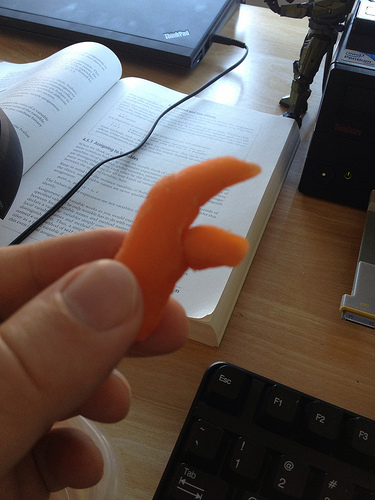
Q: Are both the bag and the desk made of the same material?
A: No, the bag is made of plastic and the desk is made of wood.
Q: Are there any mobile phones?
A: No, there are no mobile phones.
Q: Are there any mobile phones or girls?
A: No, there are no mobile phones or girls.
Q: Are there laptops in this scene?
A: Yes, there is a laptop.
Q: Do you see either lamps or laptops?
A: Yes, there is a laptop.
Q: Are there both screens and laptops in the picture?
A: No, there is a laptop but no screens.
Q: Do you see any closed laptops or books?
A: Yes, there is a closed laptop.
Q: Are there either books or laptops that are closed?
A: Yes, the laptop is closed.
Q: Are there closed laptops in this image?
A: Yes, there is a closed laptop.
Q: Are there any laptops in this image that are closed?
A: Yes, there is a laptop that is closed.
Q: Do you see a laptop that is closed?
A: Yes, there is a laptop that is closed.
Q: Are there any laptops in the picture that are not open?
A: Yes, there is an closed laptop.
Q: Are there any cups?
A: No, there are no cups.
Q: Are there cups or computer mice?
A: No, there are no cups or computer mice.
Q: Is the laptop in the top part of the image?
A: Yes, the laptop is in the top of the image.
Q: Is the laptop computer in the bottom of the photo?
A: No, the laptop computer is in the top of the image.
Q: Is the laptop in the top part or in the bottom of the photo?
A: The laptop is in the top of the image.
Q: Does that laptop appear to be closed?
A: Yes, the laptop is closed.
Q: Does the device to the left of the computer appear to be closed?
A: Yes, the laptop is closed.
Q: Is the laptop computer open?
A: No, the laptop computer is closed.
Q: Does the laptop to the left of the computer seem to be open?
A: No, the laptop computer is closed.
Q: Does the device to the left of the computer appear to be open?
A: No, the laptop computer is closed.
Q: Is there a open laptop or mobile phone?
A: No, there is a laptop but it is closed.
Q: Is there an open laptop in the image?
A: No, there is a laptop but it is closed.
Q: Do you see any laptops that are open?
A: No, there is a laptop but it is closed.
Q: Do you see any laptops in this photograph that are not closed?
A: No, there is a laptop but it is closed.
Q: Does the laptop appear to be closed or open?
A: The laptop is closed.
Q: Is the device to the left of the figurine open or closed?
A: The laptop is closed.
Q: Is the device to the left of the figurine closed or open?
A: The laptop is closed.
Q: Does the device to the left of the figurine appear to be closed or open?
A: The laptop is closed.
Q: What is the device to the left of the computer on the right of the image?
A: The device is a laptop.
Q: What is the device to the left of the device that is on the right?
A: The device is a laptop.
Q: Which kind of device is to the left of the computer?
A: The device is a laptop.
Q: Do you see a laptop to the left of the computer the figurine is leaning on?
A: Yes, there is a laptop to the left of the computer.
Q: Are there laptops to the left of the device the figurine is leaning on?
A: Yes, there is a laptop to the left of the computer.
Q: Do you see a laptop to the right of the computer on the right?
A: No, the laptop is to the left of the computer.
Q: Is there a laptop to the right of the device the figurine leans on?
A: No, the laptop is to the left of the computer.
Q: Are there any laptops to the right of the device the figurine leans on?
A: No, the laptop is to the left of the computer.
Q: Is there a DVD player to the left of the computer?
A: No, there is a laptop to the left of the computer.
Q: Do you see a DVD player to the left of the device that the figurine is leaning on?
A: No, there is a laptop to the left of the computer.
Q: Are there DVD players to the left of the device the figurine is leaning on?
A: No, there is a laptop to the left of the computer.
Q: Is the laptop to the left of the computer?
A: Yes, the laptop is to the left of the computer.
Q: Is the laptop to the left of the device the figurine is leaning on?
A: Yes, the laptop is to the left of the computer.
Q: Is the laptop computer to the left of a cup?
A: No, the laptop computer is to the left of the computer.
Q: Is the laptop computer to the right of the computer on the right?
A: No, the laptop computer is to the left of the computer.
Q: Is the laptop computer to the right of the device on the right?
A: No, the laptop computer is to the left of the computer.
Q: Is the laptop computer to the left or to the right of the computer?
A: The laptop computer is to the left of the computer.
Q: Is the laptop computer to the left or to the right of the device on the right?
A: The laptop computer is to the left of the computer.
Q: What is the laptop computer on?
A: The laptop computer is on the desk.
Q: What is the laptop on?
A: The laptop computer is on the desk.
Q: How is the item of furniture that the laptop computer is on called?
A: The piece of furniture is a desk.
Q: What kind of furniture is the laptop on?
A: The laptop computer is on the desk.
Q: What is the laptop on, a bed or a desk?
A: The laptop is on a desk.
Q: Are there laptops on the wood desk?
A: Yes, there is a laptop on the desk.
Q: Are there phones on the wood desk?
A: No, there is a laptop on the desk.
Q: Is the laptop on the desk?
A: Yes, the laptop is on the desk.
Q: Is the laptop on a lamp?
A: No, the laptop is on the desk.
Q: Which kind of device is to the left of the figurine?
A: The device is a laptop.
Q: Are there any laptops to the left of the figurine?
A: Yes, there is a laptop to the left of the figurine.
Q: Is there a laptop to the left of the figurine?
A: Yes, there is a laptop to the left of the figurine.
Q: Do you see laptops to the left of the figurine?
A: Yes, there is a laptop to the left of the figurine.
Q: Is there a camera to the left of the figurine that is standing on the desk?
A: No, there is a laptop to the left of the figurine.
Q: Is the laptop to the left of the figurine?
A: Yes, the laptop is to the left of the figurine.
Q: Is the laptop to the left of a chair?
A: No, the laptop is to the left of the figurine.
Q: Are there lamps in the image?
A: No, there are no lamps.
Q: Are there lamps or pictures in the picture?
A: No, there are no lamps or pictures.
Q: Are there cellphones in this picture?
A: No, there are no cellphones.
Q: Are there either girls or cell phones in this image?
A: No, there are no cell phones or girls.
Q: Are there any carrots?
A: Yes, there is a carrot.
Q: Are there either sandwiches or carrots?
A: Yes, there is a carrot.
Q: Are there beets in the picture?
A: No, there are no beets.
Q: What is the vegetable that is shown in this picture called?
A: The vegetable is a carrot.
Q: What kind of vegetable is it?
A: The vegetable is a carrot.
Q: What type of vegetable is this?
A: This is a carrot.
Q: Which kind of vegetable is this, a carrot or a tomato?
A: This is a carrot.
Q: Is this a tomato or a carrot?
A: This is a carrot.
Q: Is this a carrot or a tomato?
A: This is a carrot.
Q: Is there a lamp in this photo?
A: No, there are no lamps.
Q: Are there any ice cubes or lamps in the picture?
A: No, there are no lamps or ice cubes.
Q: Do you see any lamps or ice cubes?
A: No, there are no lamps or ice cubes.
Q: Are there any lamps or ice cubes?
A: No, there are no lamps or ice cubes.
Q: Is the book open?
A: Yes, the book is open.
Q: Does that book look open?
A: Yes, the book is open.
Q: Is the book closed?
A: No, the book is open.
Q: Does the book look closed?
A: No, the book is open.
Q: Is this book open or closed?
A: The book is open.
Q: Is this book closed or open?
A: The book is open.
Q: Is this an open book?
A: Yes, this is an open book.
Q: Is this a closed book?
A: No, this is an open book.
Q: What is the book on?
A: The book is on the desk.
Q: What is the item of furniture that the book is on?
A: The piece of furniture is a desk.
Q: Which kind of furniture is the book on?
A: The book is on the desk.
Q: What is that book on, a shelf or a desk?
A: The book is on a desk.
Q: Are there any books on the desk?
A: Yes, there is a book on the desk.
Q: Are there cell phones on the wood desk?
A: No, there is a book on the desk.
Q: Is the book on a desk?
A: Yes, the book is on a desk.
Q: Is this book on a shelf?
A: No, the book is on a desk.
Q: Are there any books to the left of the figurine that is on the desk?
A: Yes, there is a book to the left of the figurine.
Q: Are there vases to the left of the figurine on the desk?
A: No, there is a book to the left of the figurine.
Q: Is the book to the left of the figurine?
A: Yes, the book is to the left of the figurine.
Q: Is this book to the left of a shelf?
A: No, the book is to the left of the figurine.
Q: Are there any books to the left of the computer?
A: Yes, there is a book to the left of the computer.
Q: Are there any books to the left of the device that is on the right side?
A: Yes, there is a book to the left of the computer.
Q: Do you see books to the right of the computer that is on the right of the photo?
A: No, the book is to the left of the computer.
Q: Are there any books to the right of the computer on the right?
A: No, the book is to the left of the computer.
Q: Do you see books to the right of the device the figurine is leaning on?
A: No, the book is to the left of the computer.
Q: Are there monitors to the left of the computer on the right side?
A: No, there is a book to the left of the computer.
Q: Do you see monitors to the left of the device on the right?
A: No, there is a book to the left of the computer.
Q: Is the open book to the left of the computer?
A: Yes, the book is to the left of the computer.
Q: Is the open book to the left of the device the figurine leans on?
A: Yes, the book is to the left of the computer.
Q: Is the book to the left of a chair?
A: No, the book is to the left of the computer.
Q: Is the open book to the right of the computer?
A: No, the book is to the left of the computer.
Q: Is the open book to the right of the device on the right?
A: No, the book is to the left of the computer.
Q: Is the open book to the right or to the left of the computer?
A: The book is to the left of the computer.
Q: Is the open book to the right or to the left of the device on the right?
A: The book is to the left of the computer.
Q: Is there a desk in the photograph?
A: Yes, there is a desk.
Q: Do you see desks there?
A: Yes, there is a desk.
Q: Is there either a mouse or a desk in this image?
A: Yes, there is a desk.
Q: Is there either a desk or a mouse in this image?
A: Yes, there is a desk.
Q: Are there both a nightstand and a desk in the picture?
A: No, there is a desk but no nightstands.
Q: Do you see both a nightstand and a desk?
A: No, there is a desk but no nightstands.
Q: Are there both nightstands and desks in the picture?
A: No, there is a desk but no nightstands.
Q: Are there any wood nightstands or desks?
A: Yes, there is a wood desk.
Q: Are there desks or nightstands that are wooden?
A: Yes, the desk is wooden.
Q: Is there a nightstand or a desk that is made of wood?
A: Yes, the desk is made of wood.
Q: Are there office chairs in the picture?
A: No, there are no office chairs.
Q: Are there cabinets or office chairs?
A: No, there are no office chairs or cabinets.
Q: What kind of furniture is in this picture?
A: The furniture is a desk.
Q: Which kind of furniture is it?
A: The piece of furniture is a desk.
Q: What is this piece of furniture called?
A: This is a desk.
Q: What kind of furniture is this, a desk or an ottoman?
A: This is a desk.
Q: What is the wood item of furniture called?
A: The piece of furniture is a desk.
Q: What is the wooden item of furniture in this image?
A: The piece of furniture is a desk.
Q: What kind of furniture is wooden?
A: The furniture is a desk.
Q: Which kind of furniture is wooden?
A: The furniture is a desk.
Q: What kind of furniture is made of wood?
A: The furniture is a desk.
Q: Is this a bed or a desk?
A: This is a desk.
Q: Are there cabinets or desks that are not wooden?
A: No, there is a desk but it is wooden.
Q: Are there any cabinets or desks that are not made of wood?
A: No, there is a desk but it is made of wood.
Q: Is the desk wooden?
A: Yes, the desk is wooden.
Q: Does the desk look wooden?
A: Yes, the desk is wooden.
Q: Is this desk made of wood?
A: Yes, the desk is made of wood.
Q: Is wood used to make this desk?
A: Yes, the desk is made of wood.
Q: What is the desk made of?
A: The desk is made of wood.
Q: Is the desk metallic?
A: No, the desk is wooden.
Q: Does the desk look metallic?
A: No, the desk is wooden.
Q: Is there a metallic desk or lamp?
A: No, there is a desk but it is wooden.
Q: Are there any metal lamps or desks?
A: No, there is a desk but it is wooden.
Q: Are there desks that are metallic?
A: No, there is a desk but it is wooden.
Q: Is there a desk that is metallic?
A: No, there is a desk but it is wooden.